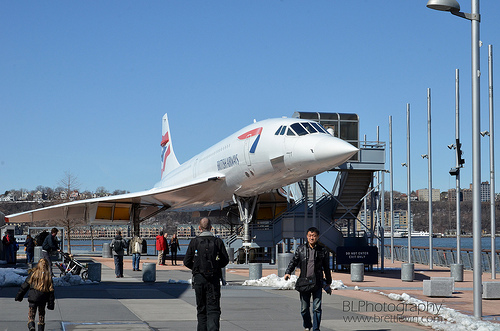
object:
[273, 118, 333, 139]
cockpit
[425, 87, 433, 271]
flag poles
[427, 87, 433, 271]
steel poles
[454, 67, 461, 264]
steel poles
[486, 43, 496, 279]
steel poles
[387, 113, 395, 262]
steel poles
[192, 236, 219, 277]
backpack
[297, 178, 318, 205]
stairway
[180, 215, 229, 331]
man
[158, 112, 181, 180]
tail-fin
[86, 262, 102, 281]
can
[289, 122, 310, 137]
windows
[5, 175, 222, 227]
wing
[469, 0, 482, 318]
pole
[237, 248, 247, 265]
wheel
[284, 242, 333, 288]
jacket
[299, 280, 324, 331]
jeans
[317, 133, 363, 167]
nose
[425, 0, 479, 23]
lamp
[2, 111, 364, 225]
jet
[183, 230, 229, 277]
coat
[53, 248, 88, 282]
trolley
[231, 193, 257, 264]
landing gear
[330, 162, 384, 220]
ladder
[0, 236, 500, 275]
waterway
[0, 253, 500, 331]
tarmac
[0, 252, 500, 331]
ground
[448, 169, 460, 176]
light